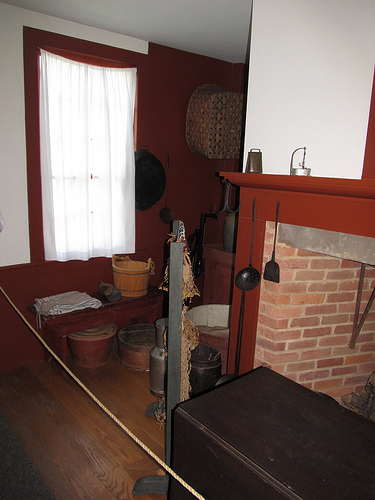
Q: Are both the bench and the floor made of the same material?
A: Yes, both the bench and the floor are made of wood.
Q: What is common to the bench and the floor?
A: The material, both the bench and the floor are wooden.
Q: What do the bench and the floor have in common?
A: The material, both the bench and the floor are wooden.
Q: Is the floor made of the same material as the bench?
A: Yes, both the floor and the bench are made of wood.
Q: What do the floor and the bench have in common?
A: The material, both the floor and the bench are wooden.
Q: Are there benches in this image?
A: Yes, there is a bench.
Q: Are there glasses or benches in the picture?
A: Yes, there is a bench.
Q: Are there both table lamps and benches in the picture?
A: No, there is a bench but no table lamps.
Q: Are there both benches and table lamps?
A: No, there is a bench but no table lamps.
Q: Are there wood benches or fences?
A: Yes, there is a wood bench.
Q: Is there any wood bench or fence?
A: Yes, there is a wood bench.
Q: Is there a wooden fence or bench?
A: Yes, there is a wood bench.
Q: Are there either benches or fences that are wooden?
A: Yes, the bench is wooden.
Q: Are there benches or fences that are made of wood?
A: Yes, the bench is made of wood.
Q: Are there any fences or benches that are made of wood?
A: Yes, the bench is made of wood.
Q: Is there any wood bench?
A: Yes, there is a bench that is made of wood.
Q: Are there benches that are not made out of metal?
A: Yes, there is a bench that is made of wood.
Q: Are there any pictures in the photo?
A: No, there are no pictures.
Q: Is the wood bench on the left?
A: Yes, the bench is on the left of the image.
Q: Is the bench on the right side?
A: No, the bench is on the left of the image.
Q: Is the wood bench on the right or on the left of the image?
A: The bench is on the left of the image.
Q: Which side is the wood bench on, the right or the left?
A: The bench is on the left of the image.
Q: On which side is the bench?
A: The bench is on the left of the image.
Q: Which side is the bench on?
A: The bench is on the left of the image.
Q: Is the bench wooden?
A: Yes, the bench is wooden.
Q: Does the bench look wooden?
A: Yes, the bench is wooden.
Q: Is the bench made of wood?
A: Yes, the bench is made of wood.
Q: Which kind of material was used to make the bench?
A: The bench is made of wood.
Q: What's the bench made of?
A: The bench is made of wood.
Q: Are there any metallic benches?
A: No, there is a bench but it is wooden.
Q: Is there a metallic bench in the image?
A: No, there is a bench but it is wooden.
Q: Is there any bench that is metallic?
A: No, there is a bench but it is wooden.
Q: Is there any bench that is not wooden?
A: No, there is a bench but it is wooden.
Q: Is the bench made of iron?
A: No, the bench is made of wood.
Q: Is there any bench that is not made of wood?
A: No, there is a bench but it is made of wood.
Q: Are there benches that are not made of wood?
A: No, there is a bench but it is made of wood.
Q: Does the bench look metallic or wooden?
A: The bench is wooden.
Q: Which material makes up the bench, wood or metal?
A: The bench is made of wood.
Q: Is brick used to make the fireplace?
A: Yes, the fireplace is made of brick.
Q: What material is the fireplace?
A: The fireplace is made of brick.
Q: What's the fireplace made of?
A: The fireplace is made of brick.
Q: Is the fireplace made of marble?
A: No, the fireplace is made of brick.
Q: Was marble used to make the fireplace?
A: No, the fireplace is made of brick.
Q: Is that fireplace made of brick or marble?
A: The fireplace is made of brick.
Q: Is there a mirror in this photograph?
A: No, there are no mirrors.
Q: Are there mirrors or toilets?
A: No, there are no mirrors or toilets.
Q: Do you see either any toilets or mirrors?
A: No, there are no mirrors or toilets.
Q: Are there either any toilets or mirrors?
A: No, there are no mirrors or toilets.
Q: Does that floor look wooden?
A: Yes, the floor is wooden.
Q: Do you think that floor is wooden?
A: Yes, the floor is wooden.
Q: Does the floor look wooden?
A: Yes, the floor is wooden.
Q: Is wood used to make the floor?
A: Yes, the floor is made of wood.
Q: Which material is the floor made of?
A: The floor is made of wood.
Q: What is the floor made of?
A: The floor is made of wood.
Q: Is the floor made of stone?
A: No, the floor is made of wood.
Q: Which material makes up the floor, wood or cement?
A: The floor is made of wood.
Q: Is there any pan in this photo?
A: Yes, there is a pan.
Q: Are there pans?
A: Yes, there is a pan.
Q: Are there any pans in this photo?
A: Yes, there is a pan.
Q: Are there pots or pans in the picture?
A: Yes, there is a pan.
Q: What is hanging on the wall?
A: The pan is hanging on the wall.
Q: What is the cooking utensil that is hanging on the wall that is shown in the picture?
A: The cooking utensil is a pan.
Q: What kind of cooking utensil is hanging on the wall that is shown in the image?
A: The cooking utensil is a pan.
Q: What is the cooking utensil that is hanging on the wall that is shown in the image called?
A: The cooking utensil is a pan.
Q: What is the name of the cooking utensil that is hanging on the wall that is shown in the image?
A: The cooking utensil is a pan.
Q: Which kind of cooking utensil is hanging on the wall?
A: The cooking utensil is a pan.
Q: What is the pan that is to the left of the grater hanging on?
A: The pan is hanging on the wall.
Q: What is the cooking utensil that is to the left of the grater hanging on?
A: The pan is hanging on the wall.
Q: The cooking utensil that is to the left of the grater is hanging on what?
A: The pan is hanging on the wall.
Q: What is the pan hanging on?
A: The pan is hanging on the wall.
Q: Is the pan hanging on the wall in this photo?
A: Yes, the pan is hanging on the wall.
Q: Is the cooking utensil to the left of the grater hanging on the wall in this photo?
A: Yes, the pan is hanging on the wall.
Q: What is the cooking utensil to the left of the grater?
A: The cooking utensil is a pan.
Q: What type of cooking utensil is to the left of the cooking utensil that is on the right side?
A: The cooking utensil is a pan.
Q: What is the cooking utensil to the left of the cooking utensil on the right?
A: The cooking utensil is a pan.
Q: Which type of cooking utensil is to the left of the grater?
A: The cooking utensil is a pan.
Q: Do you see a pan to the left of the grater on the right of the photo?
A: Yes, there is a pan to the left of the grater.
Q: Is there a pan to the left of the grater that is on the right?
A: Yes, there is a pan to the left of the grater.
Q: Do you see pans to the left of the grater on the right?
A: Yes, there is a pan to the left of the grater.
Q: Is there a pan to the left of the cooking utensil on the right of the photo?
A: Yes, there is a pan to the left of the grater.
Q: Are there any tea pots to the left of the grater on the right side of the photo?
A: No, there is a pan to the left of the grater.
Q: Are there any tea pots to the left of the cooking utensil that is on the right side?
A: No, there is a pan to the left of the grater.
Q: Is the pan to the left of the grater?
A: Yes, the pan is to the left of the grater.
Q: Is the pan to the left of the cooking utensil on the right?
A: Yes, the pan is to the left of the grater.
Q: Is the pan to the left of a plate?
A: No, the pan is to the left of the grater.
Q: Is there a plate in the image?
A: No, there are no plates.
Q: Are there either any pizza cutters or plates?
A: No, there are no plates or pizza cutters.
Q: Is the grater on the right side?
A: Yes, the grater is on the right of the image.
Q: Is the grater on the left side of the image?
A: No, the grater is on the right of the image.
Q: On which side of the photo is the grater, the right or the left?
A: The grater is on the right of the image.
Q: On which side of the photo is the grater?
A: The grater is on the right of the image.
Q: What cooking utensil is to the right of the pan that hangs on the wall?
A: The cooking utensil is a grater.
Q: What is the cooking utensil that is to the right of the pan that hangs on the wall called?
A: The cooking utensil is a grater.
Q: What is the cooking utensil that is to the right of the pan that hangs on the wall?
A: The cooking utensil is a grater.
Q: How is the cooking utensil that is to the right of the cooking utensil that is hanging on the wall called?
A: The cooking utensil is a grater.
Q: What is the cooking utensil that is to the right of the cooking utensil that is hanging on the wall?
A: The cooking utensil is a grater.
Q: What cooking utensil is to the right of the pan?
A: The cooking utensil is a grater.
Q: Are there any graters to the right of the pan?
A: Yes, there is a grater to the right of the pan.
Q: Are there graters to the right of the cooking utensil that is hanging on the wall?
A: Yes, there is a grater to the right of the pan.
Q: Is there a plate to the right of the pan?
A: No, there is a grater to the right of the pan.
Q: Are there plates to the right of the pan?
A: No, there is a grater to the right of the pan.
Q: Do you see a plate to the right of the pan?
A: No, there is a grater to the right of the pan.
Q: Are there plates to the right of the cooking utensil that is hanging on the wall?
A: No, there is a grater to the right of the pan.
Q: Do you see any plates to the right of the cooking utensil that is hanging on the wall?
A: No, there is a grater to the right of the pan.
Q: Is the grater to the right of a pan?
A: Yes, the grater is to the right of a pan.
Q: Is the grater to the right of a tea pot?
A: No, the grater is to the right of a pan.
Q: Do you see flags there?
A: No, there are no flags.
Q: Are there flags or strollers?
A: No, there are no flags or strollers.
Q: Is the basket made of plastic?
A: No, the basket is made of wicker.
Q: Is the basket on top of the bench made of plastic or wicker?
A: The basket is made of wicker.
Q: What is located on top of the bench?
A: The basket is on top of the bench.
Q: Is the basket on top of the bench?
A: Yes, the basket is on top of the bench.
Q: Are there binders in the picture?
A: No, there are no binders.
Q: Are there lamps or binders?
A: No, there are no binders or lamps.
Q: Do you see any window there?
A: Yes, there is a window.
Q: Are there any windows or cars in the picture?
A: Yes, there is a window.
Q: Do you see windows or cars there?
A: Yes, there is a window.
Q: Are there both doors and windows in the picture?
A: No, there is a window but no doors.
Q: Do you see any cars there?
A: No, there are no cars.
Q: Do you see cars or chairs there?
A: No, there are no cars or chairs.